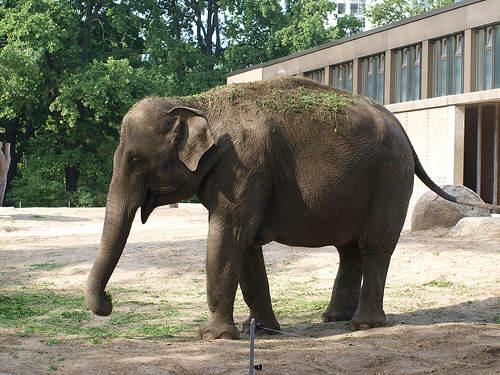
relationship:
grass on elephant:
[278, 81, 347, 129] [108, 81, 467, 305]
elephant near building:
[108, 81, 467, 305] [355, 20, 490, 110]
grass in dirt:
[278, 81, 347, 129] [129, 270, 199, 366]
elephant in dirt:
[108, 81, 467, 305] [129, 270, 199, 366]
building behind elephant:
[355, 20, 490, 110] [108, 81, 467, 305]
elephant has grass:
[108, 81, 467, 305] [278, 81, 347, 129]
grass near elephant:
[278, 81, 347, 129] [108, 81, 467, 305]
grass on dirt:
[278, 81, 347, 129] [129, 270, 199, 366]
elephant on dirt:
[108, 81, 467, 305] [129, 270, 199, 366]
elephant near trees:
[108, 81, 467, 305] [31, 11, 178, 99]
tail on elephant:
[419, 166, 497, 226] [108, 81, 467, 305]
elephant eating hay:
[108, 81, 467, 305] [112, 295, 115, 296]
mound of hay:
[0, 324, 498, 367] [273, 346, 305, 356]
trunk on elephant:
[88, 199, 137, 320] [108, 81, 467, 305]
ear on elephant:
[162, 102, 218, 171] [108, 81, 467, 305]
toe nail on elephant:
[201, 330, 211, 339] [108, 81, 467, 305]